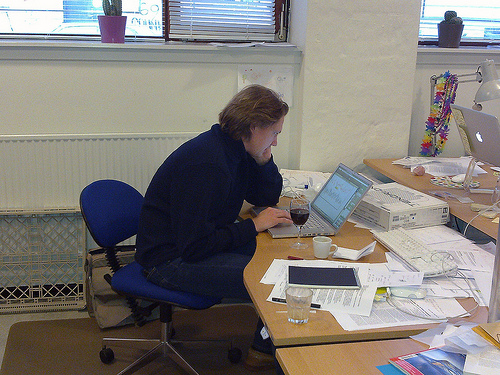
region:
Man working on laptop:
[122, 82, 390, 348]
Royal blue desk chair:
[64, 171, 136, 306]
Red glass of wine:
[274, 188, 311, 254]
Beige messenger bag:
[77, 247, 137, 332]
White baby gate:
[1, 207, 89, 315]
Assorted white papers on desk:
[362, 240, 452, 330]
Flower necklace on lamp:
[415, 65, 455, 162]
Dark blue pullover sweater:
[135, 125, 243, 281]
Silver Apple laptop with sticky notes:
[427, 84, 499, 173]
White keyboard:
[370, 231, 465, 282]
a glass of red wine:
[278, 191, 321, 248]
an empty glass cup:
[282, 283, 320, 322]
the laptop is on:
[249, 158, 391, 260]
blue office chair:
[54, 171, 229, 367]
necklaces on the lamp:
[418, 63, 476, 165]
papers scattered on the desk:
[329, 228, 485, 318]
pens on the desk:
[266, 292, 346, 317]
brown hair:
[210, 82, 301, 167]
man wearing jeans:
[150, 256, 293, 373]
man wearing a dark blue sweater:
[129, 121, 291, 258]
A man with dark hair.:
[135, 68, 289, 263]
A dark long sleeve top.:
[126, 107, 281, 256]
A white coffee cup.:
[309, 223, 339, 261]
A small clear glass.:
[281, 281, 316, 330]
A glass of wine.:
[286, 185, 311, 251]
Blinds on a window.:
[157, 7, 296, 41]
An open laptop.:
[273, 155, 368, 239]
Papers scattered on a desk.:
[332, 218, 499, 329]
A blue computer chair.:
[71, 172, 210, 317]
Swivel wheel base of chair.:
[93, 297, 247, 369]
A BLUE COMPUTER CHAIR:
[71, 181, 222, 371]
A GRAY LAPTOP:
[270, 158, 377, 240]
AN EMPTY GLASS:
[282, 274, 324, 327]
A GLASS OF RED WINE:
[284, 196, 313, 246]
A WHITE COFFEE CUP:
[308, 228, 348, 270]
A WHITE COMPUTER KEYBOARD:
[373, 221, 463, 293]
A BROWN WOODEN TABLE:
[235, 213, 471, 340]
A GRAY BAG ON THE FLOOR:
[69, 232, 181, 338]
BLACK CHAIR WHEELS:
[74, 341, 256, 371]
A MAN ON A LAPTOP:
[127, 83, 381, 309]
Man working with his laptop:
[134, 81, 376, 300]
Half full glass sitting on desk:
[285, 195, 314, 247]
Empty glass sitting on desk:
[277, 282, 317, 324]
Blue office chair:
[76, 171, 245, 373]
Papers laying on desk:
[259, 257, 499, 328]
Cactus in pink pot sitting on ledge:
[92, 0, 133, 42]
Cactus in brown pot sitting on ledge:
[433, 8, 468, 48]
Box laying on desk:
[355, 177, 452, 231]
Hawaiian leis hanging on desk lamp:
[419, 69, 462, 158]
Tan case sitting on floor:
[83, 237, 162, 331]